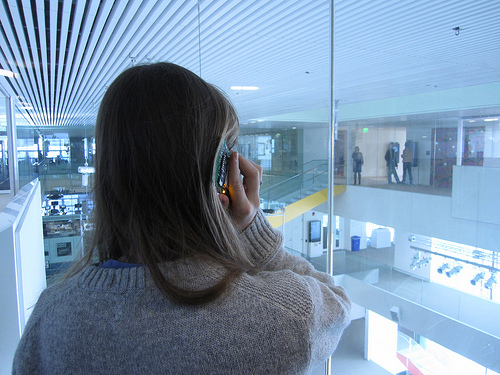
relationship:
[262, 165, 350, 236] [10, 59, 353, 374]
stairs near person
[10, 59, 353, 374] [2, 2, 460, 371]
person in hallway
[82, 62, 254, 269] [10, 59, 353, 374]
head of person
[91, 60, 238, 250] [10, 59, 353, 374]
hair of person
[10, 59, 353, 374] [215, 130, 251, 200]
person on phone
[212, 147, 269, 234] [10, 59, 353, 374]
hand of person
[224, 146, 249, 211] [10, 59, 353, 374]
finger of person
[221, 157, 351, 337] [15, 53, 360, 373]
arm of women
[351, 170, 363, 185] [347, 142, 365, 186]
legs of woman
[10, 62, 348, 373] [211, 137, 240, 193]
person talking on phone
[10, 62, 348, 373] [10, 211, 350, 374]
person wearing grey sweater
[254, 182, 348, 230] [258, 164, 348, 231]
yellow trim on stairs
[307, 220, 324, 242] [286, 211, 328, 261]
sign attached to wall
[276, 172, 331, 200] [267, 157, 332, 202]
arm rail on stairs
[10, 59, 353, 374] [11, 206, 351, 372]
person wearing sweater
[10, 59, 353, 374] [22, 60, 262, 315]
person has hair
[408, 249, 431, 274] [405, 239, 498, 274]
light hanging from bar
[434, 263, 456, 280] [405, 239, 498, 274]
light hanging from bar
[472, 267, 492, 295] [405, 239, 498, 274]
light hanging from bar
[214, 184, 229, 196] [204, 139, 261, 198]
light on phone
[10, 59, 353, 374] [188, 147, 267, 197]
person using phone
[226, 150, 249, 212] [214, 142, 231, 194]
finger on phone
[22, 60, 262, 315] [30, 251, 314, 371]
hair on back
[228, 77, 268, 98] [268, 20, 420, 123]
light on ceiling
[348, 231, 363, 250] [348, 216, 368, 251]
bin against wall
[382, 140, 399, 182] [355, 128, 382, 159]
person leaning against wall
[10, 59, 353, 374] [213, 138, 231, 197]
person talking on cell phone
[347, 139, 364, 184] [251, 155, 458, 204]
woman standing in hallway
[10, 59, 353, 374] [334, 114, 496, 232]
person looking out window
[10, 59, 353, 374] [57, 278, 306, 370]
person wearing grey sweater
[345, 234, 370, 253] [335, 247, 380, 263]
can on floor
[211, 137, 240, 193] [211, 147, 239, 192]
phone to ear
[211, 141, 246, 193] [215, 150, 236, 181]
phone to ear